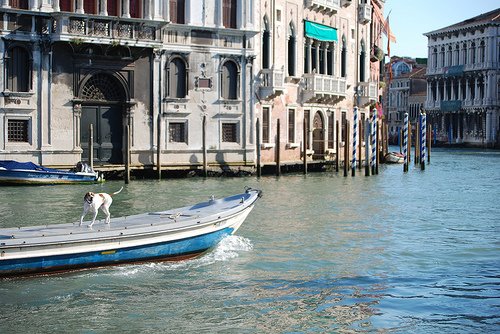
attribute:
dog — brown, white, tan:
[77, 180, 128, 227]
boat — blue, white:
[0, 185, 265, 283]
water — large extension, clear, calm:
[3, 173, 499, 333]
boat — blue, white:
[2, 157, 106, 187]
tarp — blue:
[0, 181, 259, 248]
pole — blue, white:
[348, 104, 361, 170]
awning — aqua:
[303, 21, 339, 43]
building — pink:
[370, 4, 392, 163]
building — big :
[390, 1, 499, 149]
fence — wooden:
[80, 116, 432, 177]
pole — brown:
[300, 114, 311, 181]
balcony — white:
[297, 13, 351, 107]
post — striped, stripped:
[401, 108, 413, 175]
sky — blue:
[390, 1, 476, 23]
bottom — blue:
[0, 228, 236, 276]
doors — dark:
[76, 68, 128, 166]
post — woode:
[275, 116, 283, 183]